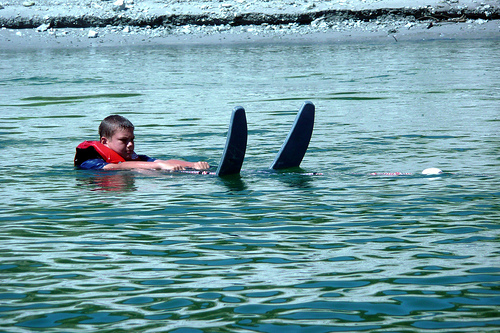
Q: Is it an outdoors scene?
A: Yes, it is outdoors.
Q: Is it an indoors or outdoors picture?
A: It is outdoors.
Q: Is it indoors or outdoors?
A: It is outdoors.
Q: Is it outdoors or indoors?
A: It is outdoors.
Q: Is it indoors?
A: No, it is outdoors.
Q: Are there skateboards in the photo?
A: No, there are no skateboards.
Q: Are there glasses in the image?
A: No, there are no glasses.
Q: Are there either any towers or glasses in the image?
A: No, there are no glasses or towers.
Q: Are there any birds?
A: No, there are no birds.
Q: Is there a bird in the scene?
A: No, there are no birds.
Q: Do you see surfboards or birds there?
A: No, there are no birds or surfboards.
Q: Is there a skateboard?
A: No, there are no skateboards.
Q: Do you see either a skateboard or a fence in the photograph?
A: No, there are no skateboards or fences.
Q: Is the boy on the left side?
A: Yes, the boy is on the left of the image.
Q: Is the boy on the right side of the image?
A: No, the boy is on the left of the image.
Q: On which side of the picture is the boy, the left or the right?
A: The boy is on the left of the image.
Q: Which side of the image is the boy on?
A: The boy is on the left of the image.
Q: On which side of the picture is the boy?
A: The boy is on the left of the image.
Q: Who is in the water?
A: The boy is in the water.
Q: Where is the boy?
A: The boy is in the water.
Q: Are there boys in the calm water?
A: Yes, there is a boy in the water.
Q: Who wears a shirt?
A: The boy wears a shirt.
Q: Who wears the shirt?
A: The boy wears a shirt.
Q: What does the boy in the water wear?
A: The boy wears a shirt.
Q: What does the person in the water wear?
A: The boy wears a shirt.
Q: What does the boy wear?
A: The boy wears a shirt.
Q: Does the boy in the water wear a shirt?
A: Yes, the boy wears a shirt.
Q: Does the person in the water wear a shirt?
A: Yes, the boy wears a shirt.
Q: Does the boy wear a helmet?
A: No, the boy wears a shirt.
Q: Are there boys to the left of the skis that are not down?
A: Yes, there is a boy to the left of the skis.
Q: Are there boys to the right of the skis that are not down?
A: No, the boy is to the left of the skis.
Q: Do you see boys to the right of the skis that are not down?
A: No, the boy is to the left of the skis.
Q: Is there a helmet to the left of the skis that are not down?
A: No, there is a boy to the left of the skis.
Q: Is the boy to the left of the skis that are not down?
A: Yes, the boy is to the left of the skis.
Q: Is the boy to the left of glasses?
A: No, the boy is to the left of the skis.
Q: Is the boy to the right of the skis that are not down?
A: No, the boy is to the left of the skis.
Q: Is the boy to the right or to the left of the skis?
A: The boy is to the left of the skis.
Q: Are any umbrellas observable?
A: No, there are no umbrellas.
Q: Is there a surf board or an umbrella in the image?
A: No, there are no umbrellas or surfboards.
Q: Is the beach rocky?
A: Yes, the beach is rocky.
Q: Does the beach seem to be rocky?
A: Yes, the beach is rocky.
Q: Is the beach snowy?
A: No, the beach is rocky.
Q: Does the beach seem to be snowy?
A: No, the beach is rocky.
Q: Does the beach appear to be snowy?
A: No, the beach is rocky.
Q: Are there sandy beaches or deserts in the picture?
A: No, there is a beach but it is rocky.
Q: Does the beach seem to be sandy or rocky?
A: The beach is rocky.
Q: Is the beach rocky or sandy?
A: The beach is rocky.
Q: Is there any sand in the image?
A: Yes, there is sand.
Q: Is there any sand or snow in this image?
A: Yes, there is sand.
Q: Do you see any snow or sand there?
A: Yes, there is sand.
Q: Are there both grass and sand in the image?
A: No, there is sand but no grass.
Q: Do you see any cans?
A: No, there are no cans.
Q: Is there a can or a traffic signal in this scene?
A: No, there are no cans or traffic lights.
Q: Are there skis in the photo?
A: Yes, there are skis.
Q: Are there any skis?
A: Yes, there are skis.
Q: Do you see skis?
A: Yes, there are skis.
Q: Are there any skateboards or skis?
A: Yes, there are skis.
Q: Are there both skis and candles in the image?
A: No, there are skis but no candles.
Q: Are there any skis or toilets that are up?
A: Yes, the skis are up.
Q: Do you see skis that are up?
A: Yes, there are skis that are up.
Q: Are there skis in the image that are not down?
A: Yes, there are skis that are up.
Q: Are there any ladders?
A: No, there are no ladders.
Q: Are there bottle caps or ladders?
A: No, there are no ladders or bottle caps.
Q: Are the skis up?
A: Yes, the skis are up.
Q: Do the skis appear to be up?
A: Yes, the skis are up.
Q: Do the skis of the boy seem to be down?
A: No, the skis are up.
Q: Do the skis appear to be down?
A: No, the skis are up.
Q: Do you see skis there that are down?
A: No, there are skis but they are up.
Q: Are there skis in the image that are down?
A: No, there are skis but they are up.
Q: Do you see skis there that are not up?
A: No, there are skis but they are up.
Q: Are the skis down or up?
A: The skis are up.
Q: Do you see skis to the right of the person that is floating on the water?
A: Yes, there are skis to the right of the person.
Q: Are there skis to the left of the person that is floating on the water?
A: No, the skis are to the right of the person.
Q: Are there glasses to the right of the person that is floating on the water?
A: No, there are skis to the right of the person.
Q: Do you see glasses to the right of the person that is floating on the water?
A: No, there are skis to the right of the person.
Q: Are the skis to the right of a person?
A: Yes, the skis are to the right of a person.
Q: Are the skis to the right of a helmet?
A: No, the skis are to the right of a person.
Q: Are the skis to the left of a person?
A: No, the skis are to the right of a person.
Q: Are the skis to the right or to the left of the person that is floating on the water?
A: The skis are to the right of the person.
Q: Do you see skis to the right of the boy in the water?
A: Yes, there are skis to the right of the boy.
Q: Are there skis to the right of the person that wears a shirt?
A: Yes, there are skis to the right of the boy.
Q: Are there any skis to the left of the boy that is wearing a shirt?
A: No, the skis are to the right of the boy.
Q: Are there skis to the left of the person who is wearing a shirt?
A: No, the skis are to the right of the boy.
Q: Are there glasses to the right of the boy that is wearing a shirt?
A: No, there are skis to the right of the boy.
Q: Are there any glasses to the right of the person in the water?
A: No, there are skis to the right of the boy.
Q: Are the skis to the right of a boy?
A: Yes, the skis are to the right of a boy.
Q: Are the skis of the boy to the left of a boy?
A: No, the skis are to the right of a boy.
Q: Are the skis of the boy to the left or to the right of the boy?
A: The skis are to the right of the boy.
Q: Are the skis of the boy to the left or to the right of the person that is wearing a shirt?
A: The skis are to the right of the boy.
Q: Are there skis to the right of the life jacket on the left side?
A: Yes, there are skis to the right of the life jacket.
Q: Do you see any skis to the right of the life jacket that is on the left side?
A: Yes, there are skis to the right of the life jacket.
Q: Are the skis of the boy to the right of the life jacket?
A: Yes, the skis are to the right of the life jacket.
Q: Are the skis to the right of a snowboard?
A: No, the skis are to the right of the life jacket.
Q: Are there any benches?
A: No, there are no benches.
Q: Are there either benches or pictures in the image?
A: No, there are no benches or pictures.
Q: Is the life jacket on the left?
A: Yes, the life jacket is on the left of the image.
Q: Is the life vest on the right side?
A: No, the life vest is on the left of the image.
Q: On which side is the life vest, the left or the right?
A: The life vest is on the left of the image.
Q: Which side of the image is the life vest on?
A: The life vest is on the left of the image.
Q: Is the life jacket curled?
A: Yes, the life jacket is curled.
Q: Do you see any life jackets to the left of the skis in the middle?
A: Yes, there is a life jacket to the left of the skis.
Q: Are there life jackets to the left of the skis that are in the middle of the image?
A: Yes, there is a life jacket to the left of the skis.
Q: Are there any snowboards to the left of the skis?
A: No, there is a life jacket to the left of the skis.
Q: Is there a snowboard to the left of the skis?
A: No, there is a life jacket to the left of the skis.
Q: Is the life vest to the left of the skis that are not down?
A: Yes, the life vest is to the left of the skis.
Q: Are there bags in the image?
A: No, there are no bags.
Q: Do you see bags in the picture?
A: No, there are no bags.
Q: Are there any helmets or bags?
A: No, there are no bags or helmets.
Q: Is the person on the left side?
A: Yes, the person is on the left of the image.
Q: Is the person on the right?
A: No, the person is on the left of the image.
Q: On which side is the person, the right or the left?
A: The person is on the left of the image.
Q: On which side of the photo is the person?
A: The person is on the left of the image.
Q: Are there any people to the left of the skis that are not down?
A: Yes, there is a person to the left of the skis.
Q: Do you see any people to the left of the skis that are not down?
A: Yes, there is a person to the left of the skis.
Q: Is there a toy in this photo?
A: No, there are no toys.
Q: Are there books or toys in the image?
A: No, there are no toys or books.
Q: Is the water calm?
A: Yes, the water is calm.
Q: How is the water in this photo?
A: The water is calm.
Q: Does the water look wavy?
A: No, the water is calm.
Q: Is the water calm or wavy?
A: The water is calm.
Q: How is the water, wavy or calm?
A: The water is calm.